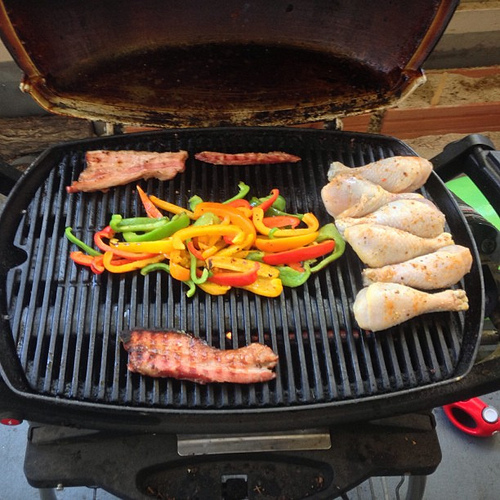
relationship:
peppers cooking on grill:
[88, 187, 328, 312] [4, 12, 484, 387]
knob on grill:
[214, 469, 254, 499] [4, 129, 494, 493]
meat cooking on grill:
[118, 327, 278, 383] [5, 136, 471, 408]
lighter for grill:
[444, 396, 484, 440] [5, 136, 471, 408]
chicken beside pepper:
[323, 150, 434, 196] [245, 200, 323, 238]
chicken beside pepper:
[319, 170, 437, 220] [247, 228, 322, 255]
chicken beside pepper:
[334, 197, 446, 242] [245, 200, 323, 238]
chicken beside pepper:
[336, 220, 457, 268] [247, 228, 322, 255]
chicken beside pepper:
[356, 239, 479, 294] [87, 222, 159, 263]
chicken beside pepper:
[356, 239, 479, 294] [247, 228, 322, 255]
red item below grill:
[439, 394, 498, 437] [5, 136, 471, 408]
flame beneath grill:
[220, 325, 235, 340] [2, 5, 498, 431]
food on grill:
[60, 173, 341, 320] [5, 136, 471, 408]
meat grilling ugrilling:
[113, 318, 282, 388] [117, 321, 279, 383]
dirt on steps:
[430, 77, 499, 135] [457, 3, 477, 133]